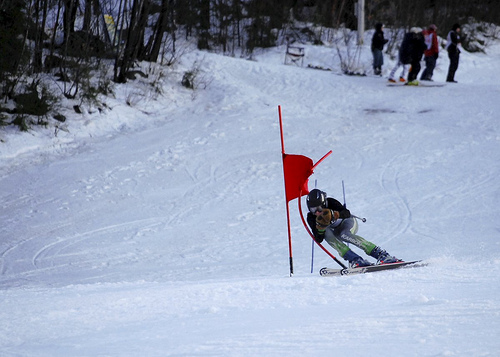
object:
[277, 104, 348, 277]
flag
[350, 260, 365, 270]
feet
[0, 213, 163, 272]
trunks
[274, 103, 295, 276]
pole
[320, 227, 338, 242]
knee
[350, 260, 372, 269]
boot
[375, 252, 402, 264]
boot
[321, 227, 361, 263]
leg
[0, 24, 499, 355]
snow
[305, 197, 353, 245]
coat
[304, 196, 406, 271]
body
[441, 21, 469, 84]
people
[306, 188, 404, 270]
man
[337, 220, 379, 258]
leg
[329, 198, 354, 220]
arm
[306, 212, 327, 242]
arm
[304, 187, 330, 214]
helmet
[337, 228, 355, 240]
knee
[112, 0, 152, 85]
trees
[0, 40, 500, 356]
ground